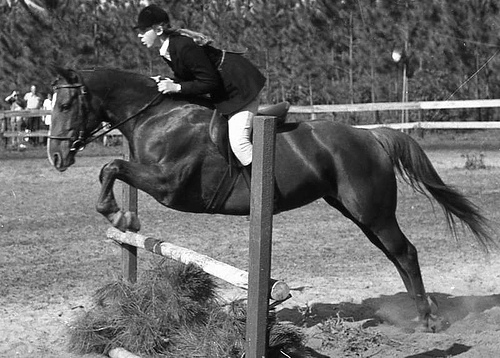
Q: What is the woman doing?
A: Riding.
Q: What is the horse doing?
A: Jumping.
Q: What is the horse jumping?
A: A pole.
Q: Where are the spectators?
A: Behind fence.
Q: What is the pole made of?
A: Wood.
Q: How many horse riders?
A: One.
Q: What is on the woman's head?
A: Hay.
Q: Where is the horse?
A: Field.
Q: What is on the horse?
A: A rider.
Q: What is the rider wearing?
A: Black helmet.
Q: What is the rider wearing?
A: Black boots.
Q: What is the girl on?
A: The horse.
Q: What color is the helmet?
A: Black.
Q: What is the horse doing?
A: Jumping over a hurdle.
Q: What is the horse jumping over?
A: A hurdle.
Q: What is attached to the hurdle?
A: Pole.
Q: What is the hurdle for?
A: Horse race.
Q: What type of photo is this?
A: Black and white.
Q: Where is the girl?
A: On the horse.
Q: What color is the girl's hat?
A: Black.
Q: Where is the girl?
A: On the horse.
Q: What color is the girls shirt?
A: White.